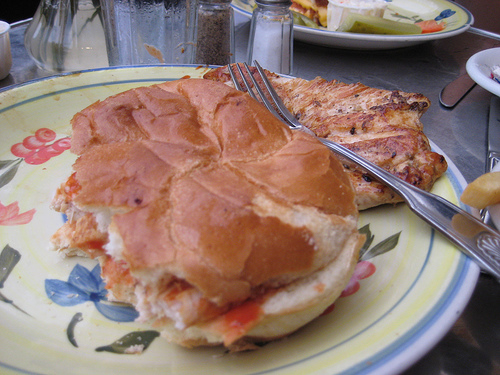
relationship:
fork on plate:
[226, 57, 498, 277] [8, 65, 483, 373]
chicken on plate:
[201, 60, 448, 211] [8, 65, 483, 373]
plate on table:
[0, 65, 484, 375] [0, 0, 499, 374]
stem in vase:
[42, 10, 75, 72] [29, 1, 121, 90]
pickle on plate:
[319, 7, 430, 34] [233, 1, 481, 57]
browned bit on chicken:
[404, 97, 423, 114] [201, 60, 448, 211]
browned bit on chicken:
[434, 150, 448, 169] [201, 60, 448, 211]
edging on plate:
[357, 108, 484, 373] [8, 65, 483, 373]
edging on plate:
[0, 53, 248, 117] [8, 65, 483, 373]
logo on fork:
[473, 232, 498, 263] [226, 57, 498, 277]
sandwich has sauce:
[51, 74, 368, 354] [204, 296, 281, 345]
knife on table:
[432, 69, 475, 119] [0, 0, 499, 374]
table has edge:
[369, 39, 496, 141] [298, 35, 498, 175]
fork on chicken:
[226, 57, 498, 277] [212, 51, 445, 228]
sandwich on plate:
[51, 74, 368, 354] [4, 262, 96, 372]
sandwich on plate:
[51, 74, 368, 354] [8, 65, 483, 373]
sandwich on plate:
[51, 74, 368, 354] [230, 0, 478, 50]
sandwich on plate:
[51, 74, 368, 354] [466, 46, 499, 98]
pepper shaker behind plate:
[190, 2, 234, 64] [8, 65, 483, 373]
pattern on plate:
[0, 121, 408, 361] [399, 257, 431, 292]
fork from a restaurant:
[226, 57, 498, 277] [0, 0, 496, 371]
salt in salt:
[250, 18, 287, 69] [250, 18, 287, 69]